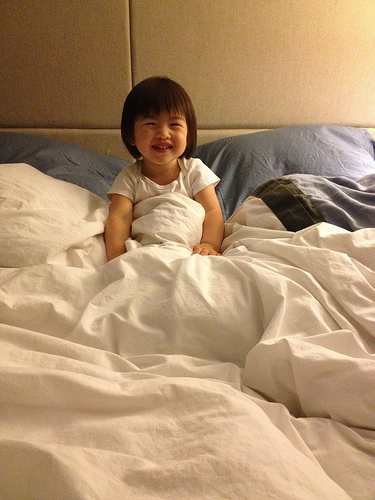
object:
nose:
[156, 123, 172, 140]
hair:
[121, 75, 199, 160]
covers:
[7, 168, 366, 446]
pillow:
[0, 131, 132, 199]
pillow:
[194, 125, 375, 218]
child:
[103, 75, 225, 262]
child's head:
[121, 75, 197, 166]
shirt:
[106, 157, 220, 199]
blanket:
[0, 162, 375, 499]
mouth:
[152, 141, 173, 153]